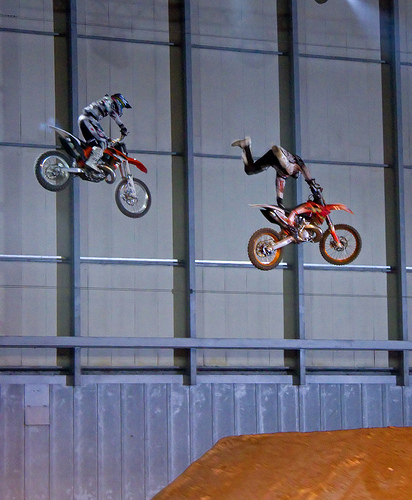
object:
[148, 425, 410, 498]
track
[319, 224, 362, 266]
wheel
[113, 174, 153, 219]
wheel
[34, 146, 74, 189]
wheel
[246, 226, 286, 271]
wheel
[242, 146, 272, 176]
leg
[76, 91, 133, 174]
people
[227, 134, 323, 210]
people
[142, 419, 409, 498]
mound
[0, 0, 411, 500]
building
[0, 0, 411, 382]
wall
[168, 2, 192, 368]
rod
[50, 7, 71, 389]
rod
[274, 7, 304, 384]
rod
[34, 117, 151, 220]
bike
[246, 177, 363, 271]
bike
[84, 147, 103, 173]
boots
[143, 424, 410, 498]
ramp